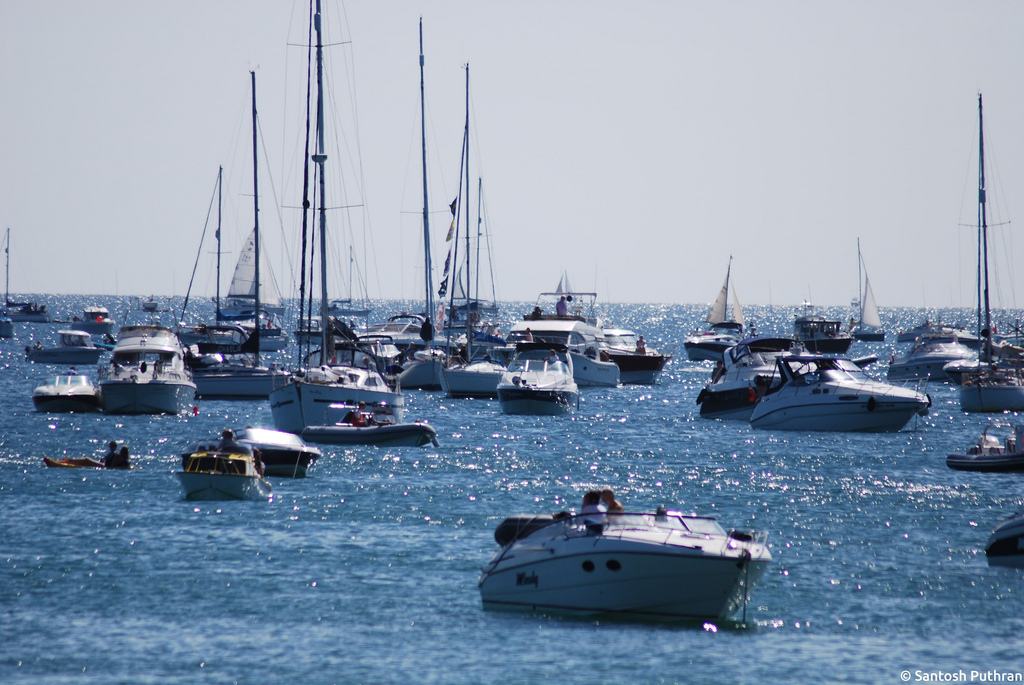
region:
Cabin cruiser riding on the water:
[469, 486, 840, 638]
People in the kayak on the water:
[29, 422, 148, 477]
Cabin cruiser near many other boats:
[712, 331, 931, 469]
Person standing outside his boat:
[516, 275, 668, 403]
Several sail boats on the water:
[140, 25, 609, 468]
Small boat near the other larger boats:
[171, 421, 283, 516]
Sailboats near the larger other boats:
[681, 221, 999, 463]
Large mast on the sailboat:
[282, 7, 375, 466]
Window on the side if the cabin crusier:
[557, 541, 653, 581]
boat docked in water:
[477, 508, 767, 625]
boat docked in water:
[747, 353, 933, 436]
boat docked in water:
[963, 94, 1021, 418]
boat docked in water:
[180, 429, 272, 498]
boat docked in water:
[228, 425, 322, 481]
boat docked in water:
[306, 398, 438, 449]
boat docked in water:
[266, 1, 398, 437]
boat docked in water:
[525, 274, 621, 388]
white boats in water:
[0, 254, 1016, 675]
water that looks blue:
[0, 288, 1022, 678]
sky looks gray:
[4, 0, 1019, 315]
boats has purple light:
[469, 478, 780, 643]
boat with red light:
[64, 299, 119, 332]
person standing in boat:
[166, 416, 271, 496]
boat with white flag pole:
[213, 51, 274, 308]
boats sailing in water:
[7, 7, 1017, 674]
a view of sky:
[556, 127, 692, 213]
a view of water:
[363, 607, 427, 640]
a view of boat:
[452, 502, 760, 632]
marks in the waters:
[410, 421, 587, 526]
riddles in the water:
[214, 487, 412, 623]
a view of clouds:
[555, 98, 784, 250]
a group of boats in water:
[123, 206, 956, 647]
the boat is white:
[454, 462, 803, 641]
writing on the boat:
[492, 552, 556, 604]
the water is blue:
[21, 285, 1008, 677]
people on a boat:
[579, 465, 634, 533]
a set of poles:
[273, 6, 369, 393]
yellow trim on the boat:
[175, 440, 262, 488]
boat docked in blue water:
[472, 445, 748, 632]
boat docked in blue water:
[175, 429, 251, 525]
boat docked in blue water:
[689, 309, 906, 455]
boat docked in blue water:
[485, 320, 600, 428]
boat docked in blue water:
[14, 344, 90, 415]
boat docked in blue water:
[90, 310, 190, 422]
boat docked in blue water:
[181, 281, 292, 392]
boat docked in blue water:
[377, 275, 432, 375]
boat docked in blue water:
[43, 320, 89, 372]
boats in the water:
[47, 206, 981, 617]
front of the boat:
[606, 483, 806, 646]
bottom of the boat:
[473, 563, 764, 637]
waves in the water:
[224, 508, 434, 651]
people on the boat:
[514, 430, 660, 544]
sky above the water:
[521, 10, 879, 207]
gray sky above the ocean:
[558, 42, 853, 180]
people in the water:
[47, 414, 166, 529]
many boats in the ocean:
[37, 193, 943, 626]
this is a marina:
[100, 93, 998, 653]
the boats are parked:
[157, 254, 611, 419]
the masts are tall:
[247, 74, 435, 280]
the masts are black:
[204, 61, 546, 350]